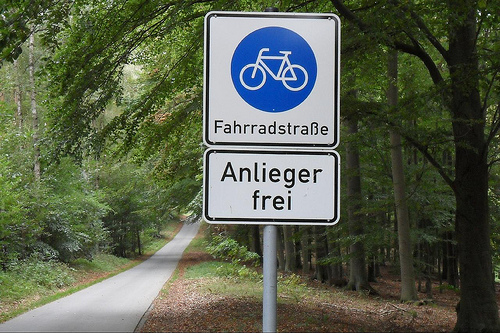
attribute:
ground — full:
[159, 281, 232, 324]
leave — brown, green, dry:
[201, 290, 226, 304]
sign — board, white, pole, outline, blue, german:
[154, 4, 366, 228]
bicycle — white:
[235, 45, 322, 95]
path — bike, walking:
[213, 110, 336, 165]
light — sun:
[166, 205, 187, 223]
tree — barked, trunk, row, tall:
[382, 69, 465, 264]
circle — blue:
[232, 25, 322, 112]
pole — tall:
[244, 223, 288, 326]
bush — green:
[8, 249, 54, 286]